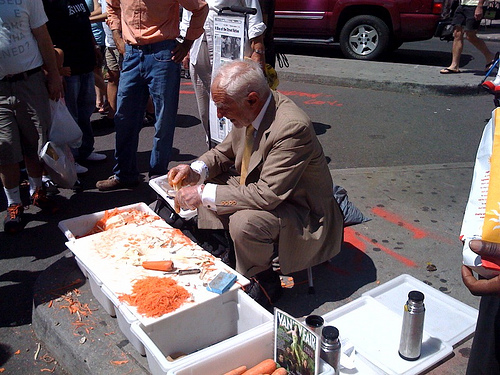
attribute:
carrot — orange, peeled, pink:
[142, 260, 173, 273]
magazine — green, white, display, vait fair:
[270, 307, 318, 371]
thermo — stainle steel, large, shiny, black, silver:
[397, 286, 426, 364]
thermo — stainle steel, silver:
[319, 321, 342, 372]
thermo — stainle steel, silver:
[309, 313, 322, 324]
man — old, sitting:
[165, 57, 339, 298]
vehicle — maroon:
[264, 2, 444, 57]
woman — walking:
[439, 0, 497, 79]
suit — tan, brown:
[194, 90, 343, 286]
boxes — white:
[55, 198, 284, 375]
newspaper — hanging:
[206, 16, 246, 148]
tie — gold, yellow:
[238, 123, 255, 186]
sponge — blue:
[207, 271, 235, 296]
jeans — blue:
[114, 35, 181, 178]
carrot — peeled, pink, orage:
[243, 353, 280, 374]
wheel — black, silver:
[337, 8, 396, 62]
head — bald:
[212, 56, 270, 134]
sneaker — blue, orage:
[1, 199, 27, 235]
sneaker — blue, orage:
[25, 190, 73, 217]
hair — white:
[214, 55, 272, 108]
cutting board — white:
[64, 219, 248, 323]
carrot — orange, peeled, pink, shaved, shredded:
[131, 275, 188, 316]